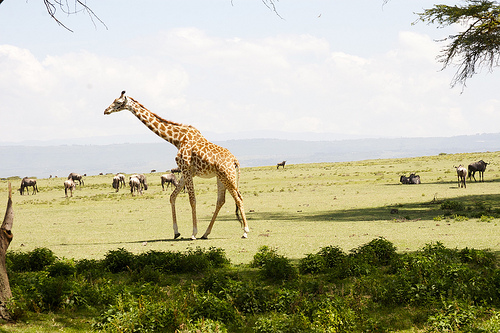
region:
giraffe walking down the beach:
[82, 82, 266, 269]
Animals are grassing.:
[17, 72, 498, 246]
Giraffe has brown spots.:
[160, 125, 213, 167]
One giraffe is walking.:
[107, 90, 278, 235]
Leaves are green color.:
[207, 273, 363, 308]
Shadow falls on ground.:
[120, 161, 480, 258]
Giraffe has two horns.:
[116, 85, 134, 106]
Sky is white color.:
[202, 50, 382, 112]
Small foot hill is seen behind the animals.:
[1, 122, 492, 178]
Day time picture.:
[37, 25, 473, 305]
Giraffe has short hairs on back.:
[143, 104, 190, 135]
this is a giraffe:
[106, 89, 253, 239]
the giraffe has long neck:
[126, 100, 187, 140]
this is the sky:
[300, 3, 377, 46]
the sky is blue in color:
[126, 5, 158, 20]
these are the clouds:
[215, 53, 305, 101]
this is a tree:
[429, 5, 498, 50]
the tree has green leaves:
[442, 7, 459, 17]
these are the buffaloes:
[21, 170, 141, 195]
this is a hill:
[306, 139, 405, 154]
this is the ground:
[288, 184, 378, 231]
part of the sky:
[218, 1, 270, 37]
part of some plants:
[323, 267, 368, 296]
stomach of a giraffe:
[197, 156, 217, 171]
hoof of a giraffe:
[240, 229, 247, 239]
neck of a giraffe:
[135, 106, 166, 135]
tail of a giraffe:
[234, 167, 249, 203]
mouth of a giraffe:
[94, 87, 117, 125]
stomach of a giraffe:
[202, 160, 214, 180]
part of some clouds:
[271, 50, 323, 91]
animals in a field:
[13, 106, 490, 321]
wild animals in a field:
[13, 85, 490, 310]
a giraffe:
[101, 85, 263, 236]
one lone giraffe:
[101, 90, 273, 245]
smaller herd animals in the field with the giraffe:
[19, 160, 494, 202]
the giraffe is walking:
[105, 80, 259, 239]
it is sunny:
[13, 13, 498, 320]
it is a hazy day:
[16, 14, 481, 174]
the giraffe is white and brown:
[97, 94, 261, 259]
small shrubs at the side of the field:
[7, 240, 493, 327]